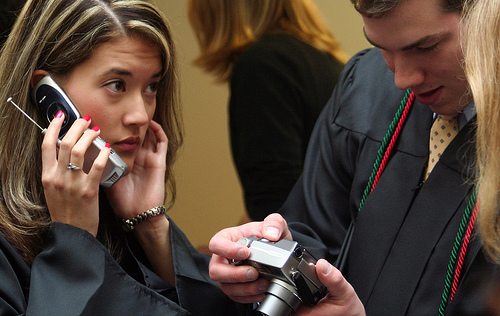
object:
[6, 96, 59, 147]
antenna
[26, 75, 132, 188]
cell phone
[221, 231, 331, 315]
camera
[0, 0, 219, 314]
woman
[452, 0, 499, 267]
hair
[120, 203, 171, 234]
bracelet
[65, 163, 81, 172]
ring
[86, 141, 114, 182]
finger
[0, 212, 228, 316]
jacket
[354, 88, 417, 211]
cord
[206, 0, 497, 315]
man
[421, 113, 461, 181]
tie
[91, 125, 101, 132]
red polish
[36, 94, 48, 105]
logo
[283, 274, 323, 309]
strap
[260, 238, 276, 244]
light